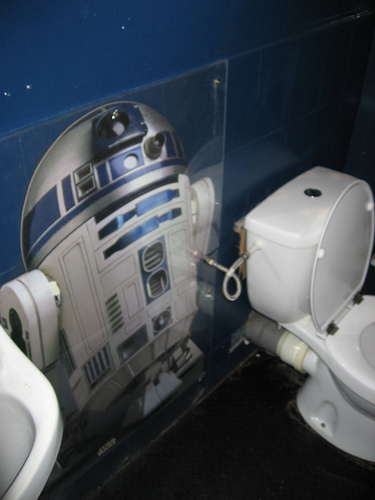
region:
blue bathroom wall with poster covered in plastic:
[4, 2, 367, 467]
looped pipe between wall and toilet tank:
[195, 237, 270, 298]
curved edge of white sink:
[0, 322, 62, 491]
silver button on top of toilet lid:
[245, 165, 350, 240]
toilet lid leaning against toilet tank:
[307, 176, 370, 327]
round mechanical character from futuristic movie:
[4, 96, 231, 419]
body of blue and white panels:
[70, 165, 186, 345]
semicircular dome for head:
[19, 92, 184, 257]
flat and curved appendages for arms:
[2, 267, 65, 369]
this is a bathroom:
[0, 44, 371, 488]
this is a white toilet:
[208, 140, 373, 464]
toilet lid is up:
[296, 181, 374, 307]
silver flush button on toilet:
[295, 175, 329, 211]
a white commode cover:
[241, 161, 362, 262]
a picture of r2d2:
[23, 85, 269, 455]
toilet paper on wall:
[0, 259, 75, 388]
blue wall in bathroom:
[7, 11, 339, 442]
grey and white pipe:
[241, 312, 327, 378]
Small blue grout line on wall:
[244, 48, 268, 149]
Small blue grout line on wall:
[286, 40, 313, 137]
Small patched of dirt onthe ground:
[239, 352, 264, 367]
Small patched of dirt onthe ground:
[278, 365, 302, 399]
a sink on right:
[0, 326, 66, 499]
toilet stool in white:
[239, 159, 374, 464]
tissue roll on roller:
[0, 268, 64, 368]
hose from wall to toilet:
[190, 237, 262, 303]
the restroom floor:
[89, 349, 373, 497]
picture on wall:
[11, 91, 224, 445]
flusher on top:
[299, 183, 326, 200]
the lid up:
[306, 176, 373, 334]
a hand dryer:
[90, 99, 148, 155]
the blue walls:
[2, 4, 371, 276]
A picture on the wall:
[0, 104, 218, 466]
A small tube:
[206, 245, 255, 299]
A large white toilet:
[244, 164, 374, 462]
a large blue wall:
[0, 0, 330, 497]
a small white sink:
[0, 322, 64, 498]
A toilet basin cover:
[242, 165, 363, 248]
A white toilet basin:
[240, 228, 317, 328]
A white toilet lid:
[306, 179, 374, 338]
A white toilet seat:
[325, 294, 374, 389]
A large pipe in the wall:
[244, 315, 311, 373]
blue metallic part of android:
[59, 172, 78, 211]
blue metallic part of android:
[91, 160, 110, 184]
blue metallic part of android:
[108, 141, 146, 179]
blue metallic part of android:
[162, 129, 175, 160]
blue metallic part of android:
[93, 184, 180, 240]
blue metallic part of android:
[96, 204, 181, 259]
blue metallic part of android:
[137, 234, 171, 303]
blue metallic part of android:
[19, 173, 67, 255]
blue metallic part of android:
[172, 129, 184, 165]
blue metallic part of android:
[87, 103, 148, 153]